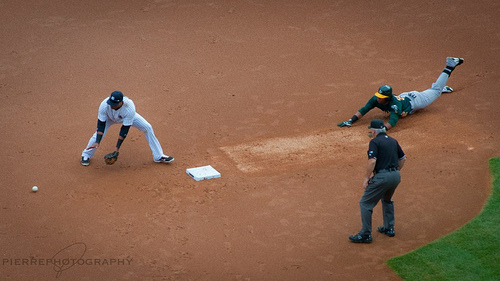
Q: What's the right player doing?
A: Sliding in.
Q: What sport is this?
A: Baseball.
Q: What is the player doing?
A: Sliding.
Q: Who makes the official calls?
A: Umpire.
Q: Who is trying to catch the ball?
A: A player.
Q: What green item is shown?
A: Grass.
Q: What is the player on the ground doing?
A: Sliding.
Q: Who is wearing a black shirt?
A: The umpire.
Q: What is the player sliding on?
A: The dirt.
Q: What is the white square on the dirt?
A: A base.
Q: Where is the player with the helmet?
A: On the ground.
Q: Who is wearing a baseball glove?
A: The player in white.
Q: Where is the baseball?
A: On the ground.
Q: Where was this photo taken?
A: At a baseball game .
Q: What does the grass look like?
A: It is green .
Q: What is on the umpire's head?
A: A black hat.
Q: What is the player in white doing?
A: Catching the ball.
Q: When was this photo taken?
A: During a baseball game.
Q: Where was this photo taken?
A: At the baseball field.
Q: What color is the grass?
A: Green.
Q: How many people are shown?
A: Three.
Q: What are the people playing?
A: Baseball.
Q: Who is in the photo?
A: Two baseball players and an umpire.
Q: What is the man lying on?
A: The ground.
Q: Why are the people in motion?
A: They are playing baseball.